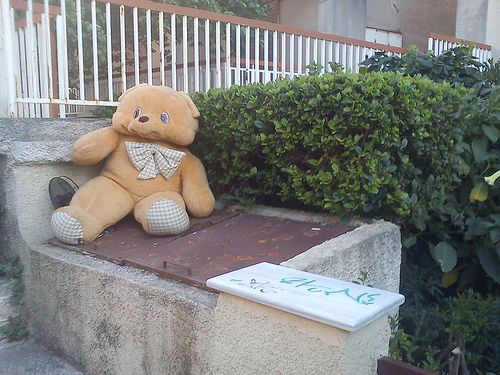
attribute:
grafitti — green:
[275, 273, 388, 304]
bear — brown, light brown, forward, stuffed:
[50, 81, 216, 250]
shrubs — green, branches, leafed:
[199, 50, 498, 227]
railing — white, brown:
[1, 2, 500, 104]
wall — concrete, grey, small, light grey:
[1, 119, 401, 375]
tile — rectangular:
[206, 259, 405, 334]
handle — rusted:
[161, 257, 197, 276]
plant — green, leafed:
[381, 289, 500, 373]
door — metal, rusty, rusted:
[118, 211, 358, 289]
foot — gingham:
[52, 212, 84, 248]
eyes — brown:
[133, 109, 168, 128]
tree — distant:
[64, 3, 270, 88]